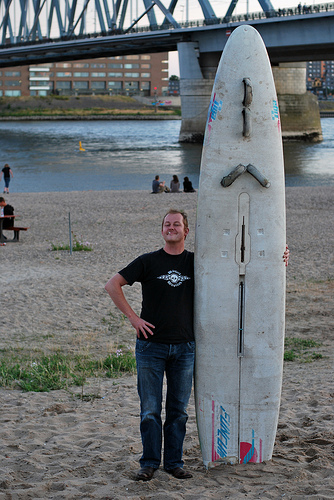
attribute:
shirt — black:
[119, 246, 196, 342]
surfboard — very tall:
[190, 25, 288, 462]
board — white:
[188, 22, 291, 473]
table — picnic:
[1, 213, 27, 236]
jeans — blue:
[133, 337, 195, 468]